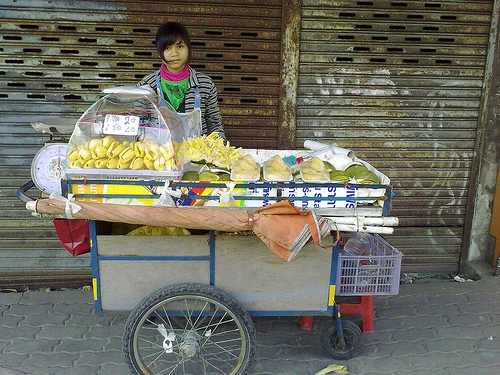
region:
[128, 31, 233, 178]
A woman standing by food cart.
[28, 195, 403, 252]
An umbrella on the side of the cart.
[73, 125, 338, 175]
Food on top of the cart.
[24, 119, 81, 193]
A scale on the edge of the cart.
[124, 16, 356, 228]
The woman is selling food on the cart.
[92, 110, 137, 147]
A white price tag for the food.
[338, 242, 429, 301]
A basket sitting on a red stool.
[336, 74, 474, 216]
Griffati on the wall.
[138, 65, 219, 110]
The lady have on a green scarf.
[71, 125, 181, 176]
The food in the plastic container is yellow.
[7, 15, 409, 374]
woman selling food in a cart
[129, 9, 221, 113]
woman has black hair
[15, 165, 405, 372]
cart is blue and small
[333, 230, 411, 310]
a basket in front a cart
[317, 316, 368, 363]
front wheel of cart is small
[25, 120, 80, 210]
a white scale on a cart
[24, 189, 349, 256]
a parasol on side of cart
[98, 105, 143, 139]
a tag with price of food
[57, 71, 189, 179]
food is covered with a cover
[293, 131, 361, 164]
a roll of paper towel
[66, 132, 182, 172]
Bananas are under the dome.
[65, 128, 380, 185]
Food is on the cart.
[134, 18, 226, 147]
A woman mans the food cart.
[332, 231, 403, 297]
A basket is on the cart.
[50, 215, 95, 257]
A bag is on the cart.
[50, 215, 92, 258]
The bag is red.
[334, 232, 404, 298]
The basket is purple.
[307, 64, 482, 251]
Graffiti is on the building.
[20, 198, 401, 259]
An umbrella is on the cart.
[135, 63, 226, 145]
The girl wears a striped shirt.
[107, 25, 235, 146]
woman standing behind cart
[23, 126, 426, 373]
mobile food cart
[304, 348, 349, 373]
trash laying on side walk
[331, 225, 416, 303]
blue plastic basket on front of cart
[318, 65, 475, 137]
white painting on metal wall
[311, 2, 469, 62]
row of holes in metal siding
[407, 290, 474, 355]
grey stones on path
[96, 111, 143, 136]
white pricing sign on side of cart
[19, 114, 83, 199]
metal scale on cart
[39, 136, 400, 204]
food displayed on top of food cart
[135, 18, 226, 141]
a young lady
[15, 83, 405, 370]
a food cart on the sidewalk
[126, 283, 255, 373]
the big wheel on the food cart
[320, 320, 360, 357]
the small wheel on the food cart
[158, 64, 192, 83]
the pink fabric around the young lady's neck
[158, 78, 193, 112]
the green fabric on the young lady's chest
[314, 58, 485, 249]
white markings on the metal wall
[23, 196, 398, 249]
a closed umbrella on the food cart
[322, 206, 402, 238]
the white pole on the side of the food cart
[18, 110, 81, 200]
the scale on the food cart